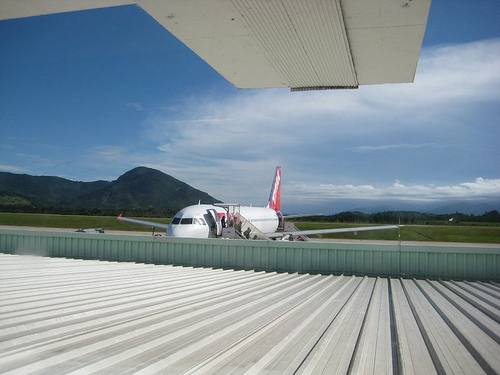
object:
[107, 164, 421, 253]
tail fin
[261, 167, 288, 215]
plane